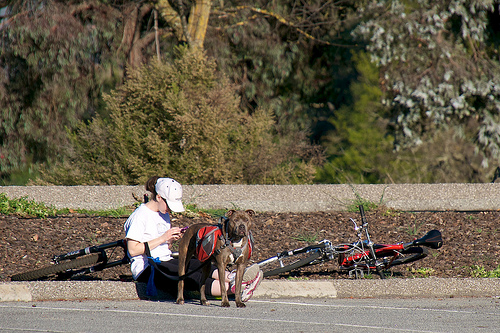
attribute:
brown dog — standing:
[185, 204, 254, 306]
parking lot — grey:
[10, 283, 472, 333]